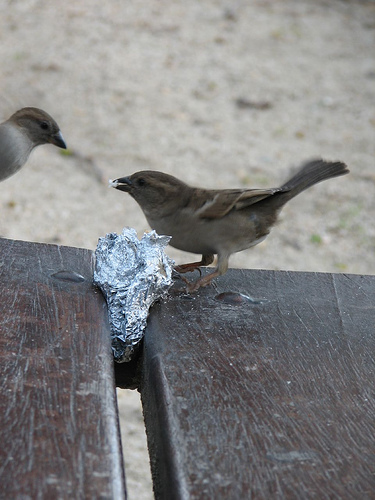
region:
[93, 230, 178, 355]
Aluminum foil on table.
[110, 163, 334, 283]
Bird with foil in its mouth.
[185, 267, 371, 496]
Brown cookout table with birds on it.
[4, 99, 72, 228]
Bird looking at bird with foil in it mouth.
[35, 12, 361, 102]
Brown kind of sandy ground.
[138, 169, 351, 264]
Bird is mostly brown with tan underbelly.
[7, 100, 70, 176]
Bird has round black eyes.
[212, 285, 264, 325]
Metal screw keeping table together.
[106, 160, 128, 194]
Bird has a black beak.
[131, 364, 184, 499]
Dirt in between table boards.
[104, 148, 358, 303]
Bird eating discarded food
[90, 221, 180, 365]
discarded trash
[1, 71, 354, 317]
Two birds competing for food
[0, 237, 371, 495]
weathered park bench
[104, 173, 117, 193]
scrap of food in bird's beak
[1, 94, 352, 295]
one bird eyeing the food of another bird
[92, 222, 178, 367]
aluminum foil stuffed into a park table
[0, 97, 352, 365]
small bird defending its find from a larger bird.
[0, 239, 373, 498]
dark brown wooden bench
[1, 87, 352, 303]
big bully bird moves in on food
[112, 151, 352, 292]
A small brown bird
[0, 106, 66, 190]
Another small brown bird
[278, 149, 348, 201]
feathery tail of the bird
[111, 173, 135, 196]
beak of the bird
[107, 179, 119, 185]
piece of foil in the bird's beak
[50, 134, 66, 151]
black beak of the bird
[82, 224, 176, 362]
Aluminum foil in a picnic table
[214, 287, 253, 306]
Bolt in the table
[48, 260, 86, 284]
Bolt in the table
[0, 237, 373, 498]
The picnic table is cracked and weathered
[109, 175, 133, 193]
a bird's small beak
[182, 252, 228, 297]
a bird's small leg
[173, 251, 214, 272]
a bird's small leg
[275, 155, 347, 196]
a bird's small tail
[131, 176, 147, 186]
a bird's small eye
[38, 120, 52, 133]
a bird's small eye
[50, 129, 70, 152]
a bird's small beak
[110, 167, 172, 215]
a bird's small head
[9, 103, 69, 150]
a bird's small head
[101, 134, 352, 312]
a small bird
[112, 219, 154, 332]
a coal in the middle of table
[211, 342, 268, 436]
a brown wooden table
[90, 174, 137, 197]
a birds beak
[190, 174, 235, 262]
a bird that is standing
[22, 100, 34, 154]
a birds face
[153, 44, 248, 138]
dirt on the ground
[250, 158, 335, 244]
a birds tail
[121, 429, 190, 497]
area between two tables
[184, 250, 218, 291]
a birds two feet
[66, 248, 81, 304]
a drop of water